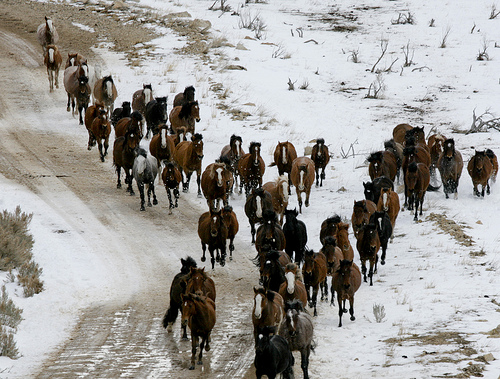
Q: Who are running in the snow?
A: The horses.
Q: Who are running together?
A: Many horses.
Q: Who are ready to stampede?
A: The horses.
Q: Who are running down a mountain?
A: Horses.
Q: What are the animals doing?
A: Horses running in snow.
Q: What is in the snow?
A: Wild horses.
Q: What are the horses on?
A: Snow.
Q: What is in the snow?
A: Horses.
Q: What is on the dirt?
A: Horses in snow.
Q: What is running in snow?
A: Wild horses.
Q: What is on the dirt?
A: Horses.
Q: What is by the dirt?
A: Mud.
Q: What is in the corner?
A: Horses in snow.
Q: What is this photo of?
A: A herd.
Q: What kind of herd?
A: A herd of horses.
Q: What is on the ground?
A: Snow.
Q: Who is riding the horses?
A: There is no one.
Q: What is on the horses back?
A: Their mane.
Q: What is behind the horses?
A: Their tails.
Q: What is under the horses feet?
A: Snow.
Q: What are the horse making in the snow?
A: Tracks.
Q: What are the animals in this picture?
A: Several horses.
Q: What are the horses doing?
A: Walking.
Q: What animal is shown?
A: Horses.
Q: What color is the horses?
A: White, black, brown.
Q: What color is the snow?
A: White.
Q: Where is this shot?
A: Street.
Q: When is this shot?
A: Daytime.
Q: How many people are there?
A: 0.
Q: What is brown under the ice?
A: Dirt.